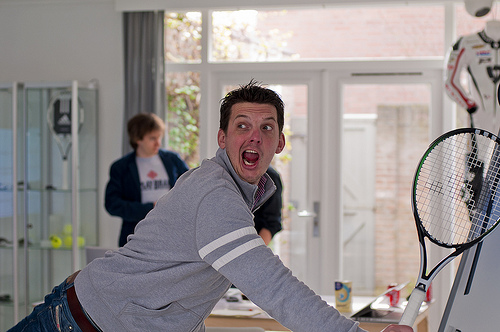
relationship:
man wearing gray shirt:
[8, 84, 415, 329] [71, 148, 369, 332]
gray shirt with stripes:
[71, 148, 369, 332] [200, 225, 263, 265]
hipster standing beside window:
[103, 110, 188, 247] [159, 11, 495, 313]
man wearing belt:
[8, 84, 415, 329] [64, 270, 100, 329]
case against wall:
[0, 77, 104, 332] [2, 0, 118, 74]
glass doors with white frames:
[211, 75, 438, 317] [200, 60, 455, 310]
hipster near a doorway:
[102, 110, 188, 247] [200, 60, 321, 312]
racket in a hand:
[398, 127, 499, 326] [377, 321, 415, 329]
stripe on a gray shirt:
[196, 226, 266, 271] [71, 148, 369, 332]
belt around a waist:
[65, 270, 99, 331] [54, 263, 117, 327]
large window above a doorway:
[204, 3, 452, 65] [201, 59, 454, 311]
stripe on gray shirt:
[196, 226, 266, 271] [71, 148, 369, 332]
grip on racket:
[398, 288, 425, 327] [400, 127, 484, 319]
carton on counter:
[332, 276, 352, 311] [203, 296, 432, 332]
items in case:
[45, 90, 90, 248] [0, 75, 102, 330]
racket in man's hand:
[398, 127, 499, 326] [385, 321, 415, 330]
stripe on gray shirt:
[196, 226, 266, 271] [67, 148, 367, 330]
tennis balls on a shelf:
[48, 221, 88, 251] [27, 242, 82, 249]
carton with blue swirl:
[335, 281, 353, 312] [336, 285, 349, 304]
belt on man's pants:
[65, 270, 99, 331] [0, 270, 94, 330]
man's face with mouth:
[220, 100, 277, 178] [237, 145, 261, 170]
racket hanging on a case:
[41, 88, 89, 189] [0, 77, 104, 332]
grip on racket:
[395, 288, 425, 327] [391, 125, 484, 322]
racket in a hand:
[400, 127, 484, 319] [377, 324, 415, 329]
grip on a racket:
[398, 288, 425, 327] [391, 125, 484, 322]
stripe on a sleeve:
[212, 237, 266, 273] [194, 185, 332, 319]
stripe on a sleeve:
[196, 226, 266, 271] [194, 185, 332, 319]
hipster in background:
[103, 110, 188, 247] [6, 16, 453, 221]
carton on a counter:
[335, 281, 353, 312] [216, 310, 421, 324]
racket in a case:
[41, 88, 89, 189] [13, 74, 102, 298]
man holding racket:
[8, 76, 415, 331] [400, 127, 484, 319]